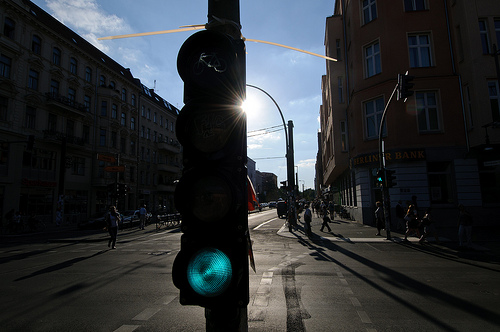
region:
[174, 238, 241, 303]
a green light on a traffic light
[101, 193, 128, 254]
a woman walking in the road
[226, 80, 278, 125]
sunlight beaming through the sky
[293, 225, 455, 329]
shadow of a light pole on the ground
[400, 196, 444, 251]
two people walking across the street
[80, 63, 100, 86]
a window on an old building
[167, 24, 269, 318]
a blank traffic light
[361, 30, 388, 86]
white frames in a window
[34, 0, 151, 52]
white faded cloud in the sky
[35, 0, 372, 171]
bright blue sky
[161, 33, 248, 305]
traffic light on pole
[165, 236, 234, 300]
green light traffic light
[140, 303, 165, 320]
white dash in road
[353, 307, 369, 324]
white dash in road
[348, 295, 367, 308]
white dash in road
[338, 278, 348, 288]
white dash in road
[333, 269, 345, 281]
white dash in road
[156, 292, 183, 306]
white dash in road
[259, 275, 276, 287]
white dash in road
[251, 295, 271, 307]
white dash in road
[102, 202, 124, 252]
person in the street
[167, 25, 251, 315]
traffic light on a pole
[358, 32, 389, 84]
window on a building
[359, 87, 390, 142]
window on a building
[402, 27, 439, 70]
window on a building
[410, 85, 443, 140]
window on a building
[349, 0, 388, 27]
window on a building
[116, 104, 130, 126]
window on a building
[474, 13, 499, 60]
window on a building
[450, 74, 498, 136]
window on a building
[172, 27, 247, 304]
a long black traffic light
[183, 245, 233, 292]
a bright green traffic light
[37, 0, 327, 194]
a light faded blue sky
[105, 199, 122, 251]
a person walking on the street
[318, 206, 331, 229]
a person walking on the sidewalk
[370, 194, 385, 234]
a person walking on the sidewalk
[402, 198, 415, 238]
a person walking on the sidewalk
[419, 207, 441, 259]
a person walking on the sidewalk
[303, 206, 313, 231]
a person walking on the sidewalk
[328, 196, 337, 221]
a person walking on the sidewalk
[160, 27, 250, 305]
Green light is on.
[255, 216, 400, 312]
Road is grey color.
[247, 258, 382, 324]
White lines are in road.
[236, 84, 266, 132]
Sun is shining brightly.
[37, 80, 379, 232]
Buildings are on both sides of the road.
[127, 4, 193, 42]
Sky is blue color.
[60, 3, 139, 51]
Clouds are white color.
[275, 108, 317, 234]
Street light is in sidewalk.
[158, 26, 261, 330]
Signal light is attached to the poles.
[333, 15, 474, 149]
Windows are attached to the building wall.